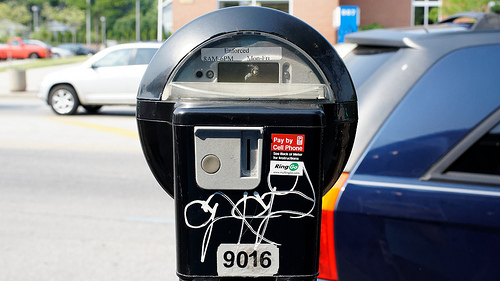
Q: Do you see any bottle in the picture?
A: No, there are no bottles.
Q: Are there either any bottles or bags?
A: No, there are no bottles or bags.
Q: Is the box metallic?
A: Yes, the box is metallic.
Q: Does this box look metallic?
A: Yes, the box is metallic.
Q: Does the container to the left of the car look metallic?
A: Yes, the box is metallic.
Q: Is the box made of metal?
A: Yes, the box is made of metal.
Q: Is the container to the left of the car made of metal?
A: Yes, the box is made of metal.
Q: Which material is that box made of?
A: The box is made of metal.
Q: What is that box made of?
A: The box is made of metal.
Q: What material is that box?
A: The box is made of metal.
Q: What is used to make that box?
A: The box is made of metal.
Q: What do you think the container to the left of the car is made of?
A: The box is made of metal.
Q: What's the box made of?
A: The box is made of metal.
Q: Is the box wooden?
A: No, the box is metallic.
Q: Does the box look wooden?
A: No, the box is metallic.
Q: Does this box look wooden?
A: No, the box is metallic.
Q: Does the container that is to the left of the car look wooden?
A: No, the box is metallic.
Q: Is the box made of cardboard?
A: No, the box is made of metal.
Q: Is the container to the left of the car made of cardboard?
A: No, the box is made of metal.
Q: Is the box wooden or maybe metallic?
A: The box is metallic.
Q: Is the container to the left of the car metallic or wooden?
A: The box is metallic.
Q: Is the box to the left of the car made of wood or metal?
A: The box is made of metal.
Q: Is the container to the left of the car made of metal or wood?
A: The box is made of metal.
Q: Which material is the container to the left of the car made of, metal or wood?
A: The box is made of metal.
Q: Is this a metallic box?
A: Yes, this is a metallic box.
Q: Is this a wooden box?
A: No, this is a metallic box.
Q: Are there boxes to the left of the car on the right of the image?
A: Yes, there is a box to the left of the car.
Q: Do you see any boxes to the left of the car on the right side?
A: Yes, there is a box to the left of the car.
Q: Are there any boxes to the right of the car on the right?
A: No, the box is to the left of the car.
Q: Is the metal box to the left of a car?
A: Yes, the box is to the left of a car.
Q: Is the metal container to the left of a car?
A: Yes, the box is to the left of a car.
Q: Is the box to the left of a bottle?
A: No, the box is to the left of a car.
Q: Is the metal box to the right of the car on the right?
A: No, the box is to the left of the car.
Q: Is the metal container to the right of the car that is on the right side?
A: No, the box is to the left of the car.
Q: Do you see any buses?
A: No, there are no buses.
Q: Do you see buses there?
A: No, there are no buses.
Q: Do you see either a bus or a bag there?
A: No, there are no buses or bags.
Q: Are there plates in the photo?
A: No, there are no plates.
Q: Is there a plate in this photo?
A: No, there are no plates.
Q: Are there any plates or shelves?
A: No, there are no plates or shelves.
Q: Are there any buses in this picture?
A: No, there are no buses.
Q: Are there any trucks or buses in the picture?
A: No, there are no buses or trucks.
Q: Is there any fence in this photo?
A: No, there are no fences.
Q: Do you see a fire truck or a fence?
A: No, there are no fences or fire trucks.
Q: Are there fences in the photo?
A: No, there are no fences.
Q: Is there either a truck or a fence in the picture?
A: No, there are no fences or trucks.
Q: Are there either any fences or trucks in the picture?
A: No, there are no fences or trucks.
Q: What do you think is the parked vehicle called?
A: The vehicle is a car.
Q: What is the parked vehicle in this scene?
A: The vehicle is a car.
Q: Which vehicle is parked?
A: The vehicle is a car.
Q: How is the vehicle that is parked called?
A: The vehicle is a car.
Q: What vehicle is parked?
A: The vehicle is a car.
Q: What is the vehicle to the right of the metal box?
A: The vehicle is a car.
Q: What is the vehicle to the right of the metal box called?
A: The vehicle is a car.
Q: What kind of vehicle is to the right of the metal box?
A: The vehicle is a car.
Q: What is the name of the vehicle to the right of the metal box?
A: The vehicle is a car.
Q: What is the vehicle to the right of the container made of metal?
A: The vehicle is a car.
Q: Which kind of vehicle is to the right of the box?
A: The vehicle is a car.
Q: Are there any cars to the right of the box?
A: Yes, there is a car to the right of the box.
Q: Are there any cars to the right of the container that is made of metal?
A: Yes, there is a car to the right of the box.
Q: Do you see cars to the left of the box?
A: No, the car is to the right of the box.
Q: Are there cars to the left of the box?
A: No, the car is to the right of the box.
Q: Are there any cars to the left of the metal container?
A: No, the car is to the right of the box.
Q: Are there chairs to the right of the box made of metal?
A: No, there is a car to the right of the box.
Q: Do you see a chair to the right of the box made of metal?
A: No, there is a car to the right of the box.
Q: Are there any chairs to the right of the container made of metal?
A: No, there is a car to the right of the box.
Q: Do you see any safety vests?
A: No, there are no safety vests.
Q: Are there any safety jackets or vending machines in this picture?
A: No, there are no safety jackets or vending machines.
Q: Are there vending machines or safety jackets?
A: No, there are no safety jackets or vending machines.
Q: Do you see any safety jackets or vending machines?
A: No, there are no safety jackets or vending machines.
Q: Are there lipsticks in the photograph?
A: No, there are no lipsticks.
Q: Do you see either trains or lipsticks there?
A: No, there are no lipsticks or trains.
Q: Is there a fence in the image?
A: No, there are no fences.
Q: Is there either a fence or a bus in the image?
A: No, there are no fences or buses.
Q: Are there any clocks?
A: No, there are no clocks.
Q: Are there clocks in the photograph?
A: No, there are no clocks.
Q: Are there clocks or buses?
A: No, there are no clocks or buses.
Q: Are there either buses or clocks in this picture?
A: No, there are no clocks or buses.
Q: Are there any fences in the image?
A: No, there are no fences.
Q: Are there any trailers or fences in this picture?
A: No, there are no fences or trailers.